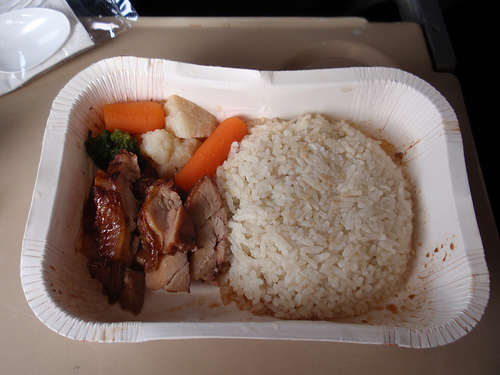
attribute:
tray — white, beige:
[261, 76, 343, 108]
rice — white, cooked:
[243, 128, 402, 303]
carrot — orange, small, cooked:
[100, 96, 174, 134]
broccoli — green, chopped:
[88, 131, 136, 155]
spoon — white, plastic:
[8, 10, 72, 56]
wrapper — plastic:
[75, 6, 117, 29]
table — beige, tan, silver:
[207, 23, 250, 57]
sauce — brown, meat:
[395, 138, 409, 166]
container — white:
[149, 62, 236, 93]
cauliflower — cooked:
[165, 104, 199, 145]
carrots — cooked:
[108, 100, 243, 150]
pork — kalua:
[142, 176, 179, 212]